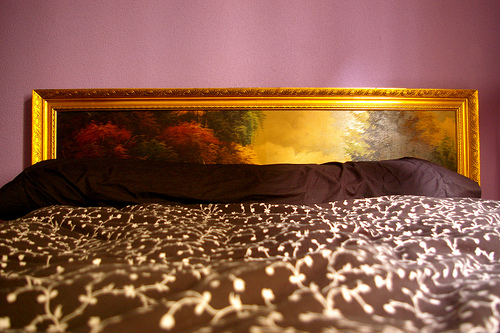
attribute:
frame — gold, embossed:
[204, 80, 246, 99]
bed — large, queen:
[62, 168, 223, 271]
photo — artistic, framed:
[80, 68, 161, 150]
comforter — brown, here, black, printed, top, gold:
[243, 162, 294, 203]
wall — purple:
[139, 23, 191, 45]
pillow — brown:
[355, 155, 412, 186]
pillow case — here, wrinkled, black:
[195, 174, 244, 213]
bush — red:
[183, 132, 199, 144]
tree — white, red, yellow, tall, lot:
[136, 231, 171, 252]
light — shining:
[344, 95, 381, 146]